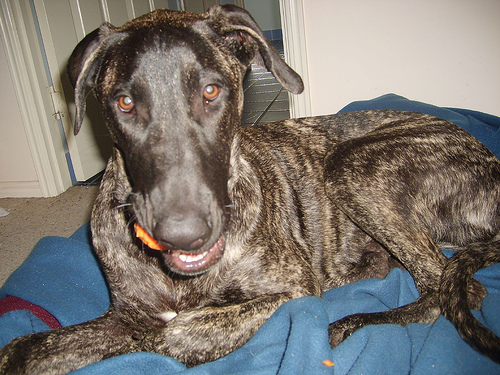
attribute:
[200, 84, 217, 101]
eye — brown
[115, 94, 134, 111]
eye — brown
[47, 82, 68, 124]
hinge — white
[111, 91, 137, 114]
eye — brown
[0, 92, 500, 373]
blanket — blue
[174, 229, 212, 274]
teeth — white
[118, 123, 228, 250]
snout — black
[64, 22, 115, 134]
ear — floppy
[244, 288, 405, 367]
blanket — blue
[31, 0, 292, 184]
door — white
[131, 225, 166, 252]
object — orange